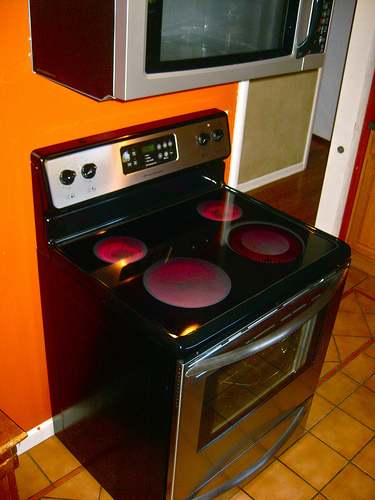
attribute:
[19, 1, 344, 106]
microwave — mounted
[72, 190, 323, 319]
burners — hot, electric, on, red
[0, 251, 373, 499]
floor — tiled, yellow, wooden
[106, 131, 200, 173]
console — digital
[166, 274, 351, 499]
door — silver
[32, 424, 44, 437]
paint — orange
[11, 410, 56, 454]
baseboard — white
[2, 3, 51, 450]
wall — orange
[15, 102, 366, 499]
oven — black, electric, silver, glass, steel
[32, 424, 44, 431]
spot — orange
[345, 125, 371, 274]
cabinet — wood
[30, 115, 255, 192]
display — steel